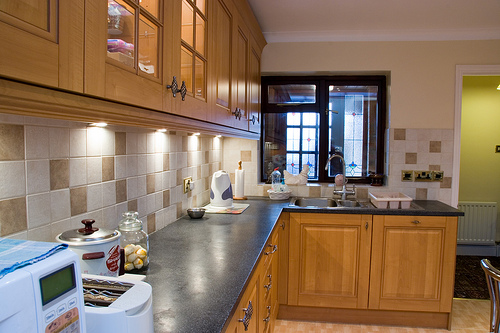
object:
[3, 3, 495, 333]
scene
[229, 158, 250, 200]
paper towel holder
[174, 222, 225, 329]
counter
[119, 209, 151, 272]
glass jar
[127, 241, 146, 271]
round items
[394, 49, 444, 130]
wall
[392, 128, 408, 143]
tiles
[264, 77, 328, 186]
windows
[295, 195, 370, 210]
sink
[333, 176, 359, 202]
faucet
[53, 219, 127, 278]
rice cooker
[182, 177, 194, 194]
outlet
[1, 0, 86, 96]
cabinets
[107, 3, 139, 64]
glass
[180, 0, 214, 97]
windows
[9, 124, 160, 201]
wall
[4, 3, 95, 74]
wood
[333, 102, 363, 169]
outside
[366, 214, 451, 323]
woden cabinets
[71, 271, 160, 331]
white toaster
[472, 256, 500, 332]
chair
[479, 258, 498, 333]
back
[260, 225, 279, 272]
drawer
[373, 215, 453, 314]
doors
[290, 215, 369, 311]
cabinet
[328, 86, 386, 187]
window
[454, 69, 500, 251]
door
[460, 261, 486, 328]
floor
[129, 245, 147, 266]
edibles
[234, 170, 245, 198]
paper towel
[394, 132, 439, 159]
beautiful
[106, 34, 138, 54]
lovely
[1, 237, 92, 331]
microwave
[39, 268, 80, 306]
digital readout area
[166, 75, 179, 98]
knobs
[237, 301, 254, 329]
handles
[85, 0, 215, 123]
two cabinets